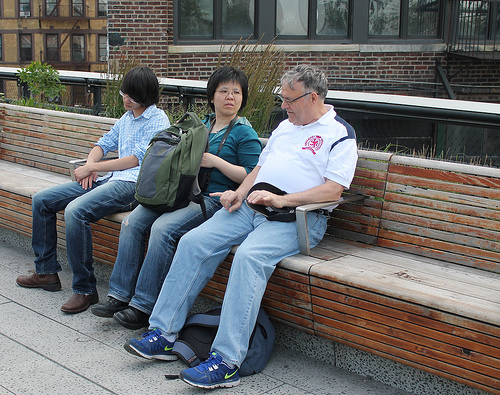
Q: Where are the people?
A: On the bench.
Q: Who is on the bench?
A: The people.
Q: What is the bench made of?
A: Wood.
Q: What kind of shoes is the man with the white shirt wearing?
A: Sneakers.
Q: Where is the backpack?
A: On the woman's lap.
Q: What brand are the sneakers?
A: Nike.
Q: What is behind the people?
A: A building.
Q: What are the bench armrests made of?
A: Metal.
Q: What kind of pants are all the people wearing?
A: Jeans.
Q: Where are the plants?
A: Behind the bench.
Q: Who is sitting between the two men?
A: A young woman.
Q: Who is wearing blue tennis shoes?
A: Older man with gray hair.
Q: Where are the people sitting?
A: On a bench.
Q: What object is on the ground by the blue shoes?
A: Backpack.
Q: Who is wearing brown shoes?
A: Man with blue checkered shirt.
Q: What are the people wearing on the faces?
A: Eyeglasses.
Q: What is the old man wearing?
A: Blue Nike tennis shoes with a green check.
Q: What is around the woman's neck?
A: A camera strap.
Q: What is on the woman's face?
A: Glasses.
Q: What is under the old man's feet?
A: A backpack.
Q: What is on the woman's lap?
A: A green backpack.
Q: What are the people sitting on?
A: A wooden bench.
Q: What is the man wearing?
A: A polo shirt and blue jeans.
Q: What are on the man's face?
A: Glasses.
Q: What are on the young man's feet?
A: Brown shoes.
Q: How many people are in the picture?
A: Three.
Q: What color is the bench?
A: Brown.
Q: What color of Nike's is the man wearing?
A: Blue.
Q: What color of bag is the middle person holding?
A: Green.